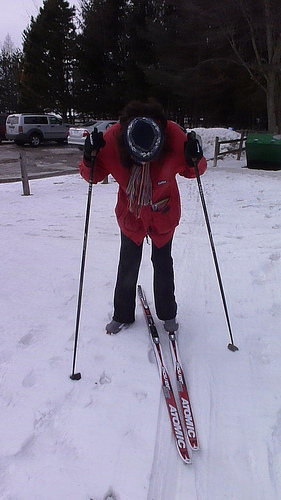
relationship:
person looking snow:
[78, 95, 207, 334] [0, 128, 279, 498]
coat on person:
[78, 116, 207, 250] [78, 95, 207, 334]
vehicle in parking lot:
[5, 112, 69, 146] [0, 119, 96, 191]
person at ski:
[78, 95, 207, 334] [164, 321, 201, 451]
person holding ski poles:
[78, 95, 207, 334] [56, 119, 248, 381]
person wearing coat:
[78, 95, 207, 334] [78, 116, 207, 250]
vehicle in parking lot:
[5, 112, 69, 147] [1, 138, 96, 191]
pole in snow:
[184, 130, 238, 350] [0, 128, 279, 498]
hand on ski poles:
[77, 124, 107, 176] [70, 126, 99, 381]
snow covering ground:
[0, 128, 279, 498] [1, 138, 280, 499]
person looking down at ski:
[68, 98, 238, 464] [136, 283, 191, 463]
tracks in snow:
[146, 403, 234, 496] [0, 128, 279, 498]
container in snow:
[240, 130, 280, 173] [0, 128, 279, 498]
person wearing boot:
[78, 95, 207, 334] [161, 313, 178, 331]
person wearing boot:
[78, 95, 207, 334] [105, 318, 125, 334]